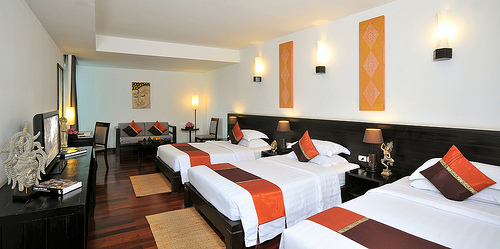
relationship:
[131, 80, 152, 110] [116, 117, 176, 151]
picture on couch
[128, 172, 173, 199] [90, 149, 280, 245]
carpet on floor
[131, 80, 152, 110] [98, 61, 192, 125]
picture hanging on wall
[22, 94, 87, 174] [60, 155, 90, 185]
television on stand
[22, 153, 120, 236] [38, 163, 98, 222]
book on stand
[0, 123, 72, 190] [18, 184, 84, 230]
art on stand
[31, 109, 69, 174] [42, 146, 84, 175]
television on stand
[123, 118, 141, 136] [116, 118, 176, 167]
pillow on couch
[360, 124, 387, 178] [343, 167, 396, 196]
lamp on table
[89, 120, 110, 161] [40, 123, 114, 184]
brown chair at desk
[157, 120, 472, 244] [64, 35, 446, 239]
three beds in room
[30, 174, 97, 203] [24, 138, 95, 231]
book on dresser